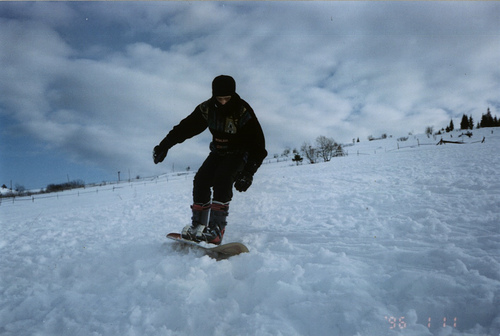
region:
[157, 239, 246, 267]
Person standing on a snowboard.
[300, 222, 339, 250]
The snow is white.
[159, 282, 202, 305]
The snow is fluffy.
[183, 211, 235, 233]
The snowboarder is wearing boots.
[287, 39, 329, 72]
Clouds in the sky.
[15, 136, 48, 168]
The sky is blue.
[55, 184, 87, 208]
A fence in the background.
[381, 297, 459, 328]
Date on the picture.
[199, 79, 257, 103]
The snowboarder is wearing a hat.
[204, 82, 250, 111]
The snowboarder is wearing a ski mask.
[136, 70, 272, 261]
snowboarder on a hill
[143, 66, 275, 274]
a person who is snowboarding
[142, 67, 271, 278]
young man who is snowboarding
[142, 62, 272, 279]
young man on a snowboard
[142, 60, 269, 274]
person on a snowboard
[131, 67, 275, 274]
person leaning while on a snowboard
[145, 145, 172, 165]
the gloved hand of a man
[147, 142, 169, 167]
the gloved hand of a snowboarder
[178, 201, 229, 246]
boots of a man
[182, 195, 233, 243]
boots of a person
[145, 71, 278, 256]
this is a man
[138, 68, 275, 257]
the man is snow skating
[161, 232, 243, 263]
the man is using a surf board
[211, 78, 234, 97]
the man is wearing a marvin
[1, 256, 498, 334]
snow is a over the place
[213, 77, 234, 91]
the marvin is black in color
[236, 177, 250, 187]
he has gloves on his hand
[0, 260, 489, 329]
the snow is white in color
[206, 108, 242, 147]
the jackets are black in color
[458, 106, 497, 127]
these are trees on the farthest part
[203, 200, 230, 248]
left boot of person on a snowboard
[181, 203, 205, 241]
right boot of person on a snowboard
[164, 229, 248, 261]
snowboard being used by the person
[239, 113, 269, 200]
left arm of person on snowboard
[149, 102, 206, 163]
right arm of person on snowboard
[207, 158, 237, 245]
left leg of person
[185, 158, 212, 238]
right leg of person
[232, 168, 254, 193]
left hand of person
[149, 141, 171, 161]
right hand of person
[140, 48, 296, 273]
snowboarder dressed in black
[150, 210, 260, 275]
object in front of snowboard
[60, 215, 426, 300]
rough texture of snow surface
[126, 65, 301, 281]
snowboarder leaning to side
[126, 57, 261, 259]
one arm raised away from body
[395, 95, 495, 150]
evergreens on top of hill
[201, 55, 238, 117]
snowboarder's eyes and nose exposed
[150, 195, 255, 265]
straps across boots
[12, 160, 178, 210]
posts for low fence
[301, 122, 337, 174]
bare branches on bushes